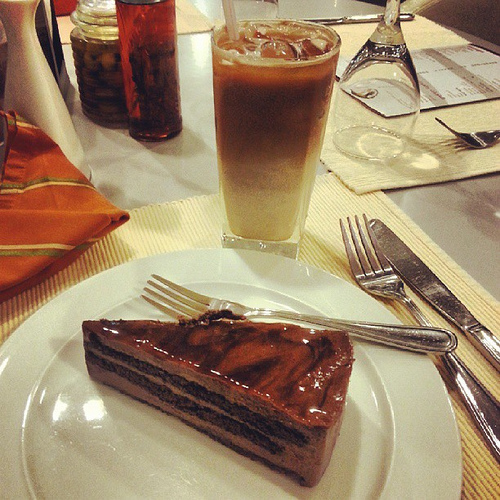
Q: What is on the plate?
A: Slice of cake.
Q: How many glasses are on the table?
A: Two.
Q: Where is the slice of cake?
A: On a plate.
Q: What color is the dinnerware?
A: White.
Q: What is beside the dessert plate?
A: Silverware.